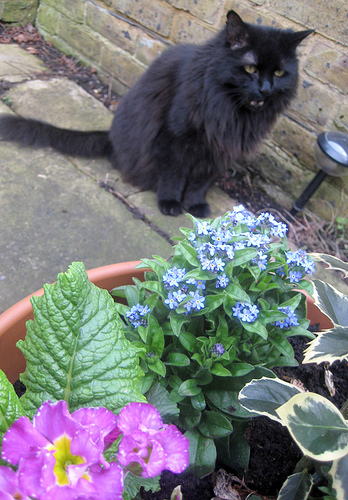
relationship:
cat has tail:
[2, 8, 316, 222] [1, 113, 110, 158]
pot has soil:
[1, 257, 347, 495] [9, 323, 346, 495]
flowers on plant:
[232, 300, 261, 323] [112, 205, 316, 409]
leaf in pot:
[274, 390, 347, 460] [1, 257, 347, 495]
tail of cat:
[1, 113, 110, 158] [2, 8, 316, 222]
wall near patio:
[3, 2, 347, 237] [1, 39, 347, 326]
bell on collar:
[248, 99, 263, 107] [205, 34, 300, 108]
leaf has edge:
[274, 390, 347, 460] [274, 409, 347, 461]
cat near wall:
[2, 8, 316, 222] [3, 2, 347, 237]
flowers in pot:
[1, 396, 190, 498] [1, 257, 347, 495]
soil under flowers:
[9, 323, 346, 495] [1, 396, 190, 498]